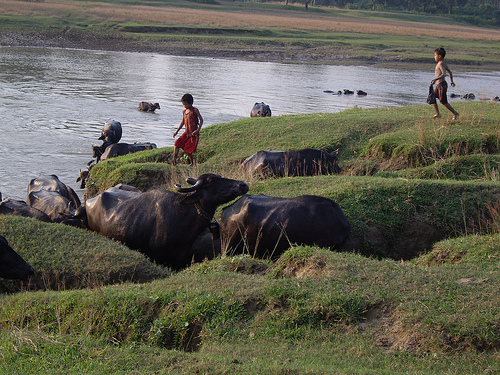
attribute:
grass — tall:
[3, 102, 498, 374]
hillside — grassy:
[0, 97, 497, 373]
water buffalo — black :
[83, 173, 248, 268]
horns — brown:
[163, 154, 203, 209]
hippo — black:
[0, 170, 90, 222]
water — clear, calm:
[0, 34, 499, 211]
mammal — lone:
[135, 94, 162, 111]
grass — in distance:
[2, 216, 161, 295]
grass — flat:
[279, 27, 372, 50]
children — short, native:
[166, 42, 461, 172]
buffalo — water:
[114, 150, 350, 288]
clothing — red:
[173, 117, 199, 153]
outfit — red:
[175, 114, 199, 152]